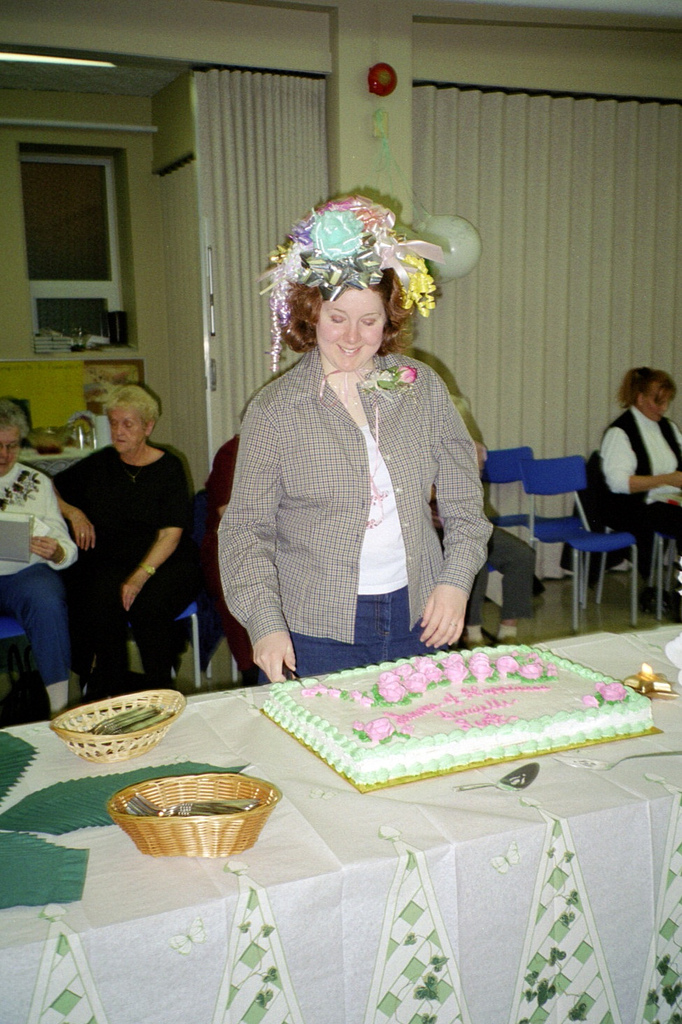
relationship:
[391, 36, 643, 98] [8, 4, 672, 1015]
wall in building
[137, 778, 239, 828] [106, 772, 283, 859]
silverware in basket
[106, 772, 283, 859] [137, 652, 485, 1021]
basket on table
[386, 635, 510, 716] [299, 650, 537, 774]
flowers on cake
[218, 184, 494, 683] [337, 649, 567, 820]
people cutting cake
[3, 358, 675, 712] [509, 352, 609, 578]
people in chairs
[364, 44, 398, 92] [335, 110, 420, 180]
firealarm on wall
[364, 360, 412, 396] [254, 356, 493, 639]
flower on jacket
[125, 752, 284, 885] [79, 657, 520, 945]
basket on table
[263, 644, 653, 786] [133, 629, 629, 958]
cake on table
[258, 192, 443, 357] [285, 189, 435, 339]
hair in hair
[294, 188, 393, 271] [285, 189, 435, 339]
ribbons in hair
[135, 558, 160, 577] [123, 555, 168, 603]
watch on wrist